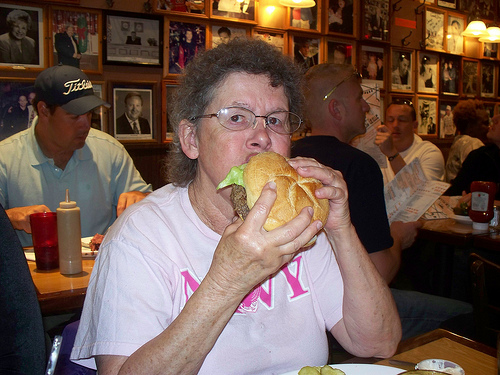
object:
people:
[67, 35, 402, 375]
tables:
[339, 328, 499, 375]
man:
[373, 98, 445, 182]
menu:
[348, 85, 387, 169]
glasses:
[388, 99, 415, 108]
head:
[384, 99, 418, 145]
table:
[21, 234, 117, 314]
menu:
[384, 156, 452, 225]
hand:
[390, 220, 423, 249]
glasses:
[189, 106, 304, 135]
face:
[198, 70, 293, 200]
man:
[287, 62, 473, 343]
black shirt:
[288, 134, 395, 253]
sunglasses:
[322, 71, 363, 101]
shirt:
[68, 178, 343, 375]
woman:
[445, 98, 490, 182]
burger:
[215, 151, 330, 248]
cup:
[29, 212, 59, 271]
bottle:
[56, 189, 83, 275]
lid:
[59, 189, 76, 209]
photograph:
[107, 78, 158, 140]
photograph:
[387, 46, 416, 94]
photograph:
[289, 31, 325, 76]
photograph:
[47, 5, 104, 75]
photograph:
[423, 5, 448, 53]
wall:
[0, 0, 500, 190]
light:
[278, 0, 316, 8]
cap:
[33, 63, 111, 116]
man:
[0, 63, 154, 341]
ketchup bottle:
[468, 181, 496, 231]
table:
[419, 195, 500, 237]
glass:
[29, 211, 58, 270]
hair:
[160, 37, 311, 187]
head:
[31, 92, 93, 151]